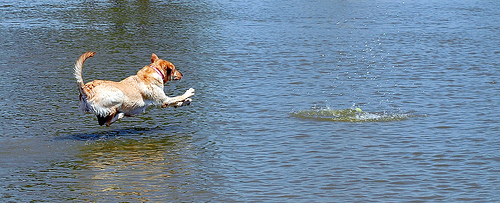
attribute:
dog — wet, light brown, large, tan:
[72, 47, 196, 127]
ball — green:
[354, 106, 362, 113]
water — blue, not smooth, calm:
[0, 0, 500, 202]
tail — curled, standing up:
[73, 49, 96, 86]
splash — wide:
[287, 77, 412, 124]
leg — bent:
[103, 111, 126, 126]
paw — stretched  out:
[186, 82, 195, 98]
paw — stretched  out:
[181, 98, 192, 108]